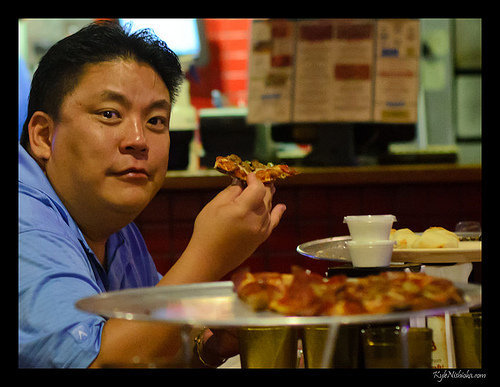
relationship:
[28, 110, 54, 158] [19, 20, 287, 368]
ear of man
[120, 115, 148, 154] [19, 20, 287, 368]
nose of man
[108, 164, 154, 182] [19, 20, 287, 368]
mouth of man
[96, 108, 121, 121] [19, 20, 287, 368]
eye of man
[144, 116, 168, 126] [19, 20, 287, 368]
eye of man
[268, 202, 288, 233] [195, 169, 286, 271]
pinky finger on right hand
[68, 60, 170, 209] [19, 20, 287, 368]
face of man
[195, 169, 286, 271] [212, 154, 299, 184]
right hand holding piece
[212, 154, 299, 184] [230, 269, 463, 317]
piece of pizza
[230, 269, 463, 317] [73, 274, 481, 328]
pizza on platter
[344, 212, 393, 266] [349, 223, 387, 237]
tubs of sauce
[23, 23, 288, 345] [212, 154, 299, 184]
man holding piece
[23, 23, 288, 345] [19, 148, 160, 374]
man wearing shirt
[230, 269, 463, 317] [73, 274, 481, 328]
pizza sitting on platter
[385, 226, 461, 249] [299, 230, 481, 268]
bread sitting on baking sheet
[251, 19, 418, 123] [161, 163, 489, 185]
menu sitting on counter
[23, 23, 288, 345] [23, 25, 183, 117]
man has hair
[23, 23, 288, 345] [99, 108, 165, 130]
man has eyes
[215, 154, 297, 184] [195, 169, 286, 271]
pizza held in right hand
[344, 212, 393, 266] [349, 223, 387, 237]
containers of sauce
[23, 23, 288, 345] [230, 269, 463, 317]
man eating pizza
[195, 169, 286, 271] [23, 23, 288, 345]
right hand of man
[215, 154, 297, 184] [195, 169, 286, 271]
pizza in right hand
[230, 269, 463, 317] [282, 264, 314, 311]
pizza topped with pepperoni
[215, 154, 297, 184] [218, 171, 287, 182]
pizza held by crust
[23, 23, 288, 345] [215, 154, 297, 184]
man eating pizza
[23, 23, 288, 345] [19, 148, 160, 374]
man in shirt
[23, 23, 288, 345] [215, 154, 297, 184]
man holding pizza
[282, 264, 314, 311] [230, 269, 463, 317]
pepperoni on pizza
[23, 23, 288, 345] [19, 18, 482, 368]
man eating in pizza parlor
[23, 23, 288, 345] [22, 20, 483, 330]
man at pizza parlor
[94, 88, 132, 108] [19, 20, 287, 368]
eyebrow of man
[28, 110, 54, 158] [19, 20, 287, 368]
right ear of man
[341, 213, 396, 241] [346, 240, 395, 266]
containers stacked on another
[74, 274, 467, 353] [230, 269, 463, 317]
platter holding pizza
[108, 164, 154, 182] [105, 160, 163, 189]
mouth with smile